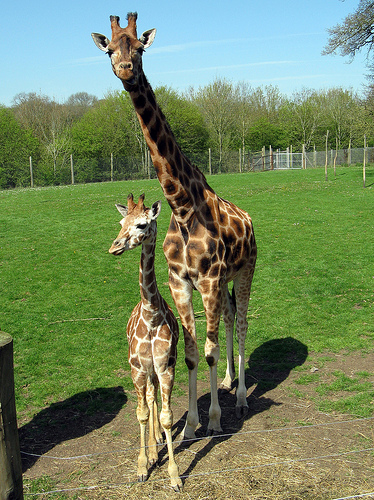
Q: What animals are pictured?
A: Giraffes.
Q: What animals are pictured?
A: Giraffes.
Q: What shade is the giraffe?
A: Brown.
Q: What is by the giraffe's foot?
A: Wire.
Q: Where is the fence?
A: In front of the giraffe.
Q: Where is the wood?
A: Next to the wire.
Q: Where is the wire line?
A: On the ground.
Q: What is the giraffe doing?
A: Looking at the camera.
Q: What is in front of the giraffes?
A: A fence.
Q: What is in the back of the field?
A: A fence.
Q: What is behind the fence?
A: Trees.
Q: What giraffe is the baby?
A: The one in front.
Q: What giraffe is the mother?
A: The one in the back.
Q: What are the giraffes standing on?
A: Dirt.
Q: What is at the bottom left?
A: A wood pole.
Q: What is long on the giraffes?
A: The necks.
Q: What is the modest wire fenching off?
A: A pen.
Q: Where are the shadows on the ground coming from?
A: The giraffes.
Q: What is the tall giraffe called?
A: Mother.